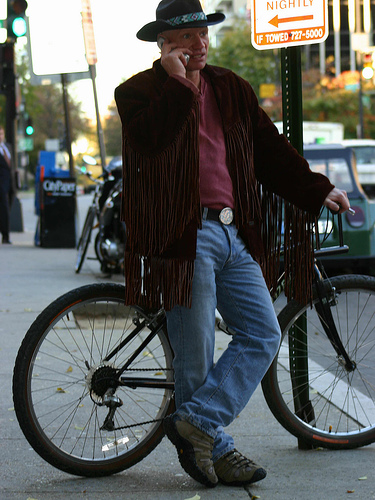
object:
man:
[114, 1, 350, 488]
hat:
[137, 0, 225, 41]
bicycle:
[12, 202, 374, 477]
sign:
[251, 0, 329, 50]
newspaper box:
[40, 175, 78, 247]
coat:
[114, 63, 333, 311]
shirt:
[177, 77, 235, 212]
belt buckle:
[219, 207, 234, 225]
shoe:
[165, 415, 218, 485]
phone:
[156, 38, 190, 63]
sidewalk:
[0, 189, 375, 499]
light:
[26, 125, 34, 135]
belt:
[199, 207, 238, 225]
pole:
[277, 46, 312, 448]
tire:
[12, 284, 175, 477]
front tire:
[261, 273, 374, 450]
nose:
[193, 32, 206, 49]